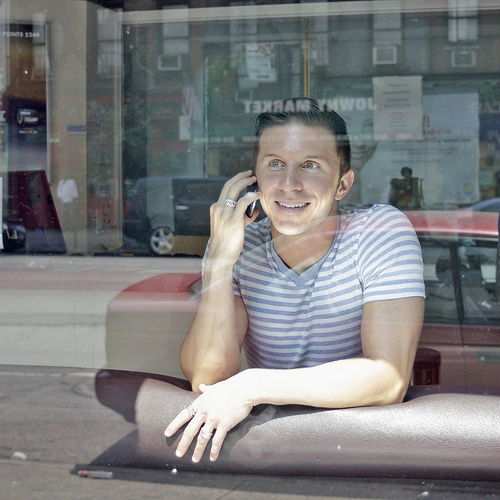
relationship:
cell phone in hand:
[233, 166, 265, 223] [186, 159, 269, 261]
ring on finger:
[223, 198, 237, 208] [232, 178, 244, 190]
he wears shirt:
[163, 96, 426, 463] [239, 221, 405, 353]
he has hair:
[163, 96, 426, 463] [338, 118, 350, 149]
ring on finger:
[223, 200, 233, 211] [169, 414, 181, 424]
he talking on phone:
[163, 96, 426, 463] [236, 170, 264, 212]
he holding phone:
[170, 74, 436, 423] [235, 187, 269, 227]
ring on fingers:
[185, 403, 197, 417] [158, 418, 217, 448]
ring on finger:
[223, 198, 237, 208] [223, 165, 243, 195]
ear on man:
[331, 167, 360, 204] [186, 107, 412, 437]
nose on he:
[273, 160, 303, 197] [163, 96, 426, 463]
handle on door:
[471, 341, 484, 349] [469, 364, 482, 382]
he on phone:
[163, 96, 426, 463] [219, 175, 264, 208]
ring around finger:
[185, 402, 198, 414] [161, 401, 200, 436]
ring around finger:
[223, 198, 237, 208] [224, 174, 255, 210]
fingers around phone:
[210, 169, 261, 228] [241, 181, 261, 213]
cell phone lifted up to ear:
[245, 166, 259, 218] [250, 163, 254, 189]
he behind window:
[163, 96, 426, 463] [2, 2, 497, 498]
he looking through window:
[163, 96, 426, 463] [2, 2, 497, 498]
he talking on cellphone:
[163, 96, 426, 463] [244, 175, 262, 213]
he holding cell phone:
[163, 96, 426, 463] [245, 166, 259, 218]